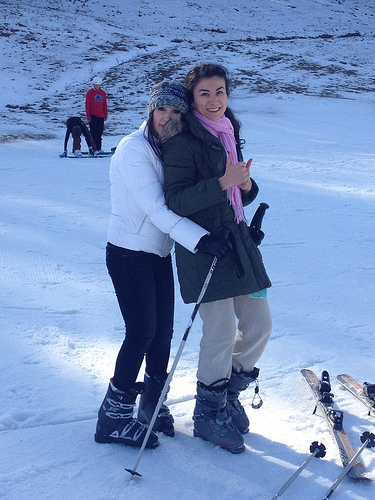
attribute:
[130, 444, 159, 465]
skis — lying, paired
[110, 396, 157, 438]
boots — gray, black, dark, grey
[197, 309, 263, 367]
pants — beige, black, light, grey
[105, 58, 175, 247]
woman — leaning, wearing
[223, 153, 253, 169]
thumbs — up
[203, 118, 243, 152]
scarf — pink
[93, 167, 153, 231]
jacket — white, black, red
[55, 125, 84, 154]
person — bending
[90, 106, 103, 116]
shirt — red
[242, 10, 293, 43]
ground — covered